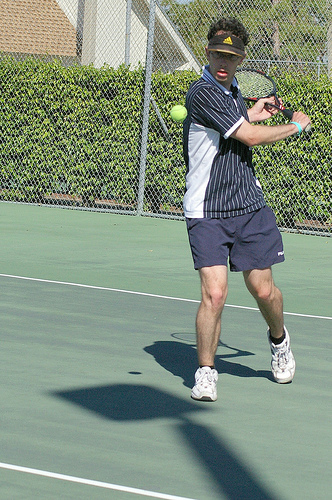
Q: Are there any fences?
A: Yes, there is a fence.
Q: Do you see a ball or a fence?
A: Yes, there is a fence.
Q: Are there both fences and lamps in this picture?
A: No, there is a fence but no lamps.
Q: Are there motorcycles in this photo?
A: No, there are no motorcycles.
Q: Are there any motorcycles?
A: No, there are no motorcycles.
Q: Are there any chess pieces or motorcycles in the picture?
A: No, there are no motorcycles or chess pieces.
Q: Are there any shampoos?
A: No, there are no shampoos.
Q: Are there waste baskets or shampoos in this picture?
A: No, there are no shampoos or waste baskets.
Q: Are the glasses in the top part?
A: Yes, the glasses are in the top of the image.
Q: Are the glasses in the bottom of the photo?
A: No, the glasses are in the top of the image.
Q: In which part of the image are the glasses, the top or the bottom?
A: The glasses are in the top of the image.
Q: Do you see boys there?
A: No, there are no boys.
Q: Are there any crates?
A: No, there are no crates.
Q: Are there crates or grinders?
A: No, there are no crates or grinders.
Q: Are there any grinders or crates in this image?
A: No, there are no crates or grinders.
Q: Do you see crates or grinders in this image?
A: No, there are no crates or grinders.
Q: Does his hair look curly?
A: Yes, the hair is curly.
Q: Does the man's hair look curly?
A: Yes, the hair is curly.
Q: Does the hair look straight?
A: No, the hair is curly.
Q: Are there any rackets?
A: Yes, there is a racket.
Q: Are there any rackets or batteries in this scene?
A: Yes, there is a racket.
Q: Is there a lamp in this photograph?
A: No, there are no lamps.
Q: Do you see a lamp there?
A: No, there are no lamps.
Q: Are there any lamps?
A: No, there are no lamps.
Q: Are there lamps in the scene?
A: No, there are no lamps.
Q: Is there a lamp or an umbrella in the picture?
A: No, there are no lamps or umbrellas.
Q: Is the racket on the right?
A: Yes, the racket is on the right of the image.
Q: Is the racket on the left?
A: No, the racket is on the right of the image.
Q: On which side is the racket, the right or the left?
A: The racket is on the right of the image.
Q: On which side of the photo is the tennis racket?
A: The tennis racket is on the right of the image.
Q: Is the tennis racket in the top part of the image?
A: Yes, the tennis racket is in the top of the image.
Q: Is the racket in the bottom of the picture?
A: No, the racket is in the top of the image.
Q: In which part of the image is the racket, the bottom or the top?
A: The racket is in the top of the image.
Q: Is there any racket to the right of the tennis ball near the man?
A: Yes, there is a racket to the right of the tennis ball.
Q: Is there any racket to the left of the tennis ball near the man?
A: No, the racket is to the right of the tennis ball.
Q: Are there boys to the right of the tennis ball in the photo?
A: No, there is a racket to the right of the tennis ball.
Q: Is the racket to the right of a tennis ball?
A: Yes, the racket is to the right of a tennis ball.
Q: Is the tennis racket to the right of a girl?
A: No, the tennis racket is to the right of a tennis ball.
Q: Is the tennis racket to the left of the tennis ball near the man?
A: No, the tennis racket is to the right of the tennis ball.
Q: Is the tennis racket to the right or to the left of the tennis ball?
A: The tennis racket is to the right of the tennis ball.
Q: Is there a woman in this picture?
A: No, there are no women.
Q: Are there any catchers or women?
A: No, there are no women or catchers.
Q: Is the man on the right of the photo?
A: Yes, the man is on the right of the image.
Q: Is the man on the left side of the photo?
A: No, the man is on the right of the image.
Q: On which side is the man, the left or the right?
A: The man is on the right of the image.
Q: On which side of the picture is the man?
A: The man is on the right of the image.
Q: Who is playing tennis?
A: The man is playing tennis.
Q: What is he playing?
A: The man is playing tennis.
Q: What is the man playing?
A: The man is playing tennis.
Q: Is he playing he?
A: Yes, the man is playing tennis.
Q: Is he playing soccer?
A: No, the man is playing tennis.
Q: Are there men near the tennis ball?
A: Yes, there is a man near the tennis ball.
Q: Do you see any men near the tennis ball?
A: Yes, there is a man near the tennis ball.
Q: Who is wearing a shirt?
A: The man is wearing a shirt.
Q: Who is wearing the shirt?
A: The man is wearing a shirt.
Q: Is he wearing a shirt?
A: Yes, the man is wearing a shirt.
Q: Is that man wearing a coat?
A: No, the man is wearing a shirt.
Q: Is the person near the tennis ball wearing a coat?
A: No, the man is wearing a shirt.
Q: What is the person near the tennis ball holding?
A: The man is holding the racket.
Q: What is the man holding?
A: The man is holding the racket.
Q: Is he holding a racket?
A: Yes, the man is holding a racket.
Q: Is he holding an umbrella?
A: No, the man is holding a racket.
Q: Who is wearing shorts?
A: The man is wearing shorts.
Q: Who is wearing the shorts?
A: The man is wearing shorts.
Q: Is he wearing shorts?
A: Yes, the man is wearing shorts.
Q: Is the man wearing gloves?
A: No, the man is wearing shorts.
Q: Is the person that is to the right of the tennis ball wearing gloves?
A: No, the man is wearing shorts.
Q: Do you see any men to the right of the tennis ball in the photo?
A: Yes, there is a man to the right of the tennis ball.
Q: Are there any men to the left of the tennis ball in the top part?
A: No, the man is to the right of the tennis ball.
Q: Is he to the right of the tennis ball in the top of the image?
A: Yes, the man is to the right of the tennis ball.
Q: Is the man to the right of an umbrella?
A: No, the man is to the right of the tennis ball.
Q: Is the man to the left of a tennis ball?
A: No, the man is to the right of a tennis ball.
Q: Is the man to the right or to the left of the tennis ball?
A: The man is to the right of the tennis ball.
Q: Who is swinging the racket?
A: The man is swinging the racket.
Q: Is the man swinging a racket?
A: Yes, the man is swinging a racket.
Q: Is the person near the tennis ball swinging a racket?
A: Yes, the man is swinging a racket.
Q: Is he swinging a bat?
A: No, the man is swinging a racket.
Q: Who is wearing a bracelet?
A: The man is wearing a bracelet.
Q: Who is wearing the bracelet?
A: The man is wearing a bracelet.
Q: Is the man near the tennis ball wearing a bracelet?
A: Yes, the man is wearing a bracelet.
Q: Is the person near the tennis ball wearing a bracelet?
A: Yes, the man is wearing a bracelet.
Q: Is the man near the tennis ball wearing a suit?
A: No, the man is wearing a bracelet.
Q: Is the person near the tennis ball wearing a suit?
A: No, the man is wearing a bracelet.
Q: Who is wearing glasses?
A: The man is wearing glasses.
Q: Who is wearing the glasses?
A: The man is wearing glasses.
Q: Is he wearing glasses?
A: Yes, the man is wearing glasses.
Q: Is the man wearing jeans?
A: No, the man is wearing glasses.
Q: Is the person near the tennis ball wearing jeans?
A: No, the man is wearing glasses.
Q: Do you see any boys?
A: No, there are no boys.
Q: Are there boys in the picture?
A: No, there are no boys.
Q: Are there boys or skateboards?
A: No, there are no boys or skateboards.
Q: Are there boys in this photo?
A: No, there are no boys.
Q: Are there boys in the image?
A: No, there are no boys.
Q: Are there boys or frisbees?
A: No, there are no boys or frisbees.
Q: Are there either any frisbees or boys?
A: No, there are no boys or frisbees.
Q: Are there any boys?
A: No, there are no boys.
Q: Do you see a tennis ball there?
A: Yes, there is a tennis ball.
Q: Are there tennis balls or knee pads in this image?
A: Yes, there is a tennis ball.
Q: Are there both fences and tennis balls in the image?
A: Yes, there are both a tennis ball and a fence.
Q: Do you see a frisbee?
A: No, there are no frisbees.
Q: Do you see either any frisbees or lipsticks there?
A: No, there are no frisbees or lipsticks.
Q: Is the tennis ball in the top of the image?
A: Yes, the tennis ball is in the top of the image.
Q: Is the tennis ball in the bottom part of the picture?
A: No, the tennis ball is in the top of the image.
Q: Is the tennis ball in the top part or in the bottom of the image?
A: The tennis ball is in the top of the image.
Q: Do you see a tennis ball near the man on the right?
A: Yes, there is a tennis ball near the man.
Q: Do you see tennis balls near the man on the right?
A: Yes, there is a tennis ball near the man.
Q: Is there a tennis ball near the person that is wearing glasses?
A: Yes, there is a tennis ball near the man.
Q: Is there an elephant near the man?
A: No, there is a tennis ball near the man.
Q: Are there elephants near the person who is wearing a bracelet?
A: No, there is a tennis ball near the man.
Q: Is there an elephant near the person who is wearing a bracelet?
A: No, there is a tennis ball near the man.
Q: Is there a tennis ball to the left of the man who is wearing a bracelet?
A: Yes, there is a tennis ball to the left of the man.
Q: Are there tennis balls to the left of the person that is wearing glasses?
A: Yes, there is a tennis ball to the left of the man.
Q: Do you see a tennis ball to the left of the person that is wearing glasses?
A: Yes, there is a tennis ball to the left of the man.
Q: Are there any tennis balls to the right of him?
A: No, the tennis ball is to the left of the man.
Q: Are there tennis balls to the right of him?
A: No, the tennis ball is to the left of the man.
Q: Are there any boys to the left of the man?
A: No, there is a tennis ball to the left of the man.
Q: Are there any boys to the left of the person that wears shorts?
A: No, there is a tennis ball to the left of the man.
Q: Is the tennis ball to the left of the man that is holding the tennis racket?
A: Yes, the tennis ball is to the left of the man.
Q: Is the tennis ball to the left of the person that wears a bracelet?
A: Yes, the tennis ball is to the left of the man.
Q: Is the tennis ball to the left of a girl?
A: No, the tennis ball is to the left of the man.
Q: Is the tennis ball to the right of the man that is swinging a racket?
A: No, the tennis ball is to the left of the man.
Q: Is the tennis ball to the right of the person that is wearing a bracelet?
A: No, the tennis ball is to the left of the man.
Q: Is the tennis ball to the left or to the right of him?
A: The tennis ball is to the left of the man.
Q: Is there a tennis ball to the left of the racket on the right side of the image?
A: Yes, there is a tennis ball to the left of the tennis racket.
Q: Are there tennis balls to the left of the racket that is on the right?
A: Yes, there is a tennis ball to the left of the tennis racket.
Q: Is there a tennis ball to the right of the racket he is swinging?
A: No, the tennis ball is to the left of the racket.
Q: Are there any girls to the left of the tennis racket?
A: No, there is a tennis ball to the left of the tennis racket.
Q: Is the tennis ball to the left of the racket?
A: Yes, the tennis ball is to the left of the racket.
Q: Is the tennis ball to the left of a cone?
A: No, the tennis ball is to the left of the racket.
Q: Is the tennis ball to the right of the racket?
A: No, the tennis ball is to the left of the racket.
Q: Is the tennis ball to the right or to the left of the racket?
A: The tennis ball is to the left of the racket.